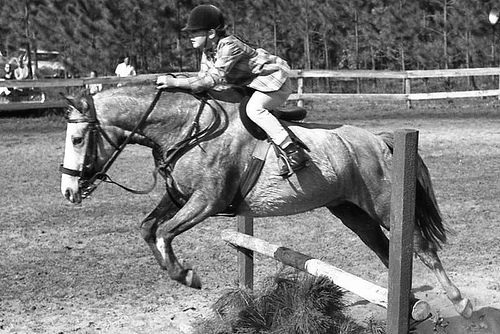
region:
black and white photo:
[29, 6, 487, 311]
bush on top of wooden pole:
[224, 230, 420, 332]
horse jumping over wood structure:
[57, 64, 467, 326]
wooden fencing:
[362, 44, 492, 114]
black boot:
[267, 125, 328, 190]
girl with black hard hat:
[170, 2, 286, 84]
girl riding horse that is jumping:
[36, 5, 408, 271]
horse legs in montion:
[128, 175, 229, 306]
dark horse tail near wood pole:
[366, 120, 481, 275]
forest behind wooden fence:
[357, 7, 487, 119]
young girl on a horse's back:
[154, 5, 314, 177]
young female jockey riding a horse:
[57, 3, 475, 331]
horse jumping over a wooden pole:
[58, 85, 472, 320]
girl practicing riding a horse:
[2, 2, 495, 329]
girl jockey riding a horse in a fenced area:
[60, 4, 475, 332]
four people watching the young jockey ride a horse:
[2, 54, 137, 111]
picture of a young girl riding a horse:
[1, 2, 498, 327]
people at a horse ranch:
[4, 2, 495, 332]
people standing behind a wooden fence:
[1, 53, 136, 111]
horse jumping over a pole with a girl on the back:
[56, 3, 473, 332]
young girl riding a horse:
[39, 3, 482, 329]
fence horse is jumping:
[217, 218, 445, 331]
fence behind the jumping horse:
[305, 53, 498, 111]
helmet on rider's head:
[176, 0, 232, 39]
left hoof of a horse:
[167, 268, 211, 290]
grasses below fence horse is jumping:
[218, 266, 350, 332]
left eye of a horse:
[67, 128, 88, 150]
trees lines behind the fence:
[13, 1, 167, 43]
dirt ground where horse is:
[432, 111, 498, 181]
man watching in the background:
[103, 51, 143, 78]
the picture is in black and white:
[0, 0, 495, 320]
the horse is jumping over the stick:
[40, 5, 475, 300]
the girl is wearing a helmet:
[170, 5, 230, 45]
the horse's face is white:
[55, 100, 90, 205]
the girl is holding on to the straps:
[150, 0, 335, 175]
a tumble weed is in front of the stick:
[180, 251, 345, 326]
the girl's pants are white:
[240, 70, 305, 146]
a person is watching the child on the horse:
[95, 35, 146, 100]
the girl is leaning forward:
[155, 0, 337, 150]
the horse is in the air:
[33, 70, 489, 319]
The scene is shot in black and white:
[0, 1, 499, 333]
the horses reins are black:
[58, 70, 229, 201]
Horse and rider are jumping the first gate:
[57, 3, 478, 324]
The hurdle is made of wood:
[220, 125, 435, 331]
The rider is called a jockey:
[153, 7, 315, 179]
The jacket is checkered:
[182, 32, 291, 99]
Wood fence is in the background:
[1, 62, 499, 117]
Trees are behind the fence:
[1, 4, 498, 95]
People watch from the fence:
[0, 44, 136, 116]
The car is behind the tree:
[13, 41, 67, 86]